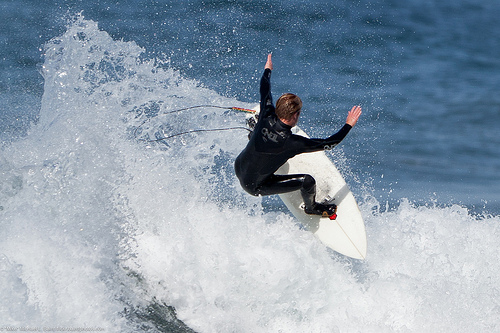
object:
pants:
[234, 163, 337, 218]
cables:
[149, 101, 257, 118]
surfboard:
[236, 87, 366, 260]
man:
[231, 48, 361, 219]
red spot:
[328, 213, 341, 220]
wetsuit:
[218, 66, 352, 216]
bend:
[232, 51, 362, 217]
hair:
[274, 92, 301, 121]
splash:
[11, 13, 500, 333]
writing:
[259, 126, 279, 143]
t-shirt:
[232, 68, 350, 165]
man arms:
[259, 66, 280, 112]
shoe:
[303, 201, 337, 215]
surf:
[230, 45, 371, 267]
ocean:
[2, 5, 498, 327]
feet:
[302, 201, 337, 217]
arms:
[298, 122, 354, 154]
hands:
[340, 103, 362, 126]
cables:
[153, 126, 255, 140]